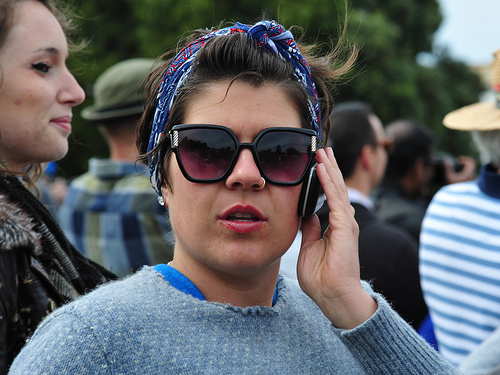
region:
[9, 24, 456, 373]
a woman holding a cellphone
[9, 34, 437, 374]
a woman talking on a cellphone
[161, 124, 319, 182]
dark purple tinted sunglasses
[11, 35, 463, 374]
a woman wearing a blue sweater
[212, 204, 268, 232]
red lipstick applied to her lips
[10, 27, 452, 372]
a woman sports a nose ring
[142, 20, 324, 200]
a red, white, and blue bandana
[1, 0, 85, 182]
a woman who has a slight smile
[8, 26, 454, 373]
a woman staring at the photographer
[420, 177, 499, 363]
a blue and white striped shirt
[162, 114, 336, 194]
sunglasses on woman on phone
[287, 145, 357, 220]
cellphone on woman's ear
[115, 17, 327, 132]
bandana around woman's head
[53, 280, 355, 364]
blue sweater on woman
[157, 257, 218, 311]
blue t shirt under sweater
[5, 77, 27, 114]
acne on woman's face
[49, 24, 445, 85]
green trees in background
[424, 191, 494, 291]
blue striped shirt on person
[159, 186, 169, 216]
earring on woman's ear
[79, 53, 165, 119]
green hat in background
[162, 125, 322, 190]
sunglasses on a woman's face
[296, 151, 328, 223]
a cellphone in a woman's hand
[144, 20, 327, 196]
a headband wrapped around a woman's head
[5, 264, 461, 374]
a blue sweater on a woman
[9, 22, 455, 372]
a woman talking on the phone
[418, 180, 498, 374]
a white shirt with blue stripes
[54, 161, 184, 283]
a blue plaid shirton a man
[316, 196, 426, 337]
a suitcoat on a man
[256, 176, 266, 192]
a nose ring in a woman's nose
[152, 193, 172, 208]
a diamond earring in a woman's ear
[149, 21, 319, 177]
a blue head band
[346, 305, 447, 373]
a blue sleeve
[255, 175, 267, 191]
a nose ring in her nostril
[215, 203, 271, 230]
pink lipstick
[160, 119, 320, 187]
black sunglasses on her face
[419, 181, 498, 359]
a blue and white striped shirt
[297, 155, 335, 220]
a cell phone on her ear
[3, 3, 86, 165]
the woman is smiling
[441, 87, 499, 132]
the brim of a hat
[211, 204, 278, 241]
her mouth is open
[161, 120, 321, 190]
Purple tinted glasses.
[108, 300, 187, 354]
The sweater is thick and blue.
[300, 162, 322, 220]
A small cell phone.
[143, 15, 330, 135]
The woman is wearing a blue head band.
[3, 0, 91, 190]
This woman is smiling.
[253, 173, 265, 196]
A nose ring in the left nostril.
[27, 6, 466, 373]
A woman talking on a cell phone.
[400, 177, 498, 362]
A man wearing a striped shirt.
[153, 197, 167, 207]
A small diamond earring.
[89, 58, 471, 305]
A crowd waits in line.